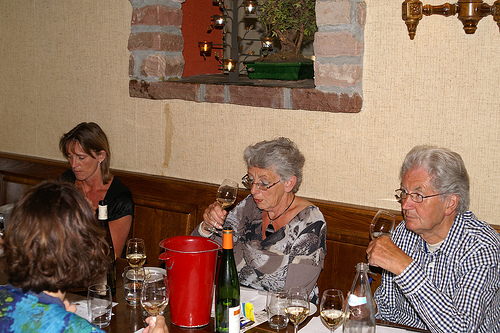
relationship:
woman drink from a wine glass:
[234, 142, 327, 294] [217, 179, 237, 208]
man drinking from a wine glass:
[392, 147, 499, 332] [369, 207, 394, 264]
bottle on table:
[220, 223, 239, 332] [1, 271, 383, 332]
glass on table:
[91, 285, 112, 326] [1, 271, 383, 332]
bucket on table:
[161, 236, 218, 327] [1, 271, 383, 332]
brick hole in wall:
[135, 5, 355, 111] [2, 3, 499, 213]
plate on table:
[127, 267, 167, 282] [1, 271, 383, 332]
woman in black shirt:
[61, 125, 133, 252] [62, 177, 136, 215]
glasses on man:
[398, 188, 429, 204] [392, 147, 499, 332]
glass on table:
[125, 237, 148, 287] [1, 271, 383, 332]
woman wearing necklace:
[234, 142, 327, 294] [265, 212, 277, 236]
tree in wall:
[251, 4, 312, 79] [2, 3, 499, 213]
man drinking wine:
[392, 147, 499, 332] [375, 236, 390, 243]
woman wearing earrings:
[61, 125, 133, 252] [97, 160, 103, 165]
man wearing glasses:
[392, 147, 499, 332] [398, 188, 429, 204]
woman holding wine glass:
[234, 142, 327, 294] [217, 179, 237, 208]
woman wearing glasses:
[234, 142, 327, 294] [241, 181, 281, 192]